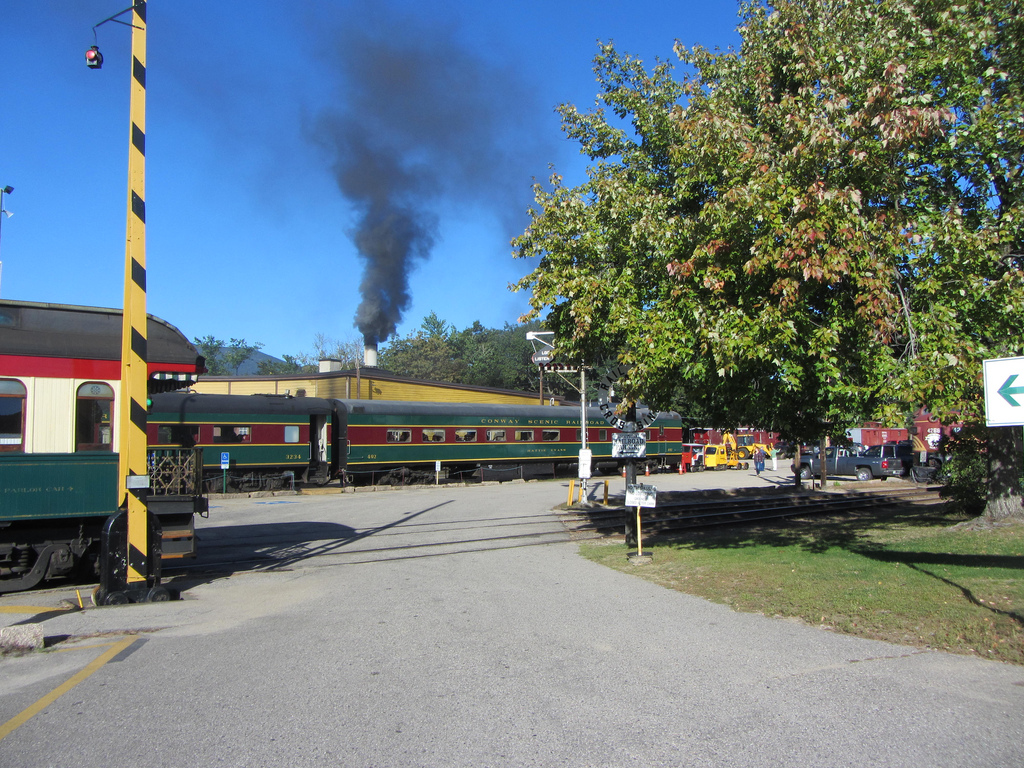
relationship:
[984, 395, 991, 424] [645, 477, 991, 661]
sign on grass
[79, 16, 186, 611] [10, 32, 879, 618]
beam in air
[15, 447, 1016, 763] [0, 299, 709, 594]
road beside train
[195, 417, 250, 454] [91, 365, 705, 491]
window of train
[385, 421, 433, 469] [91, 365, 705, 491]
window of train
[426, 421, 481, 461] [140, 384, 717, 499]
window of train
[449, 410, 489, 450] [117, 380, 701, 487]
window of train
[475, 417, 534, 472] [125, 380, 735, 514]
window of train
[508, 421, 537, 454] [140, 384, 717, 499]
window of train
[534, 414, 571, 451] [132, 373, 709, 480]
window of train